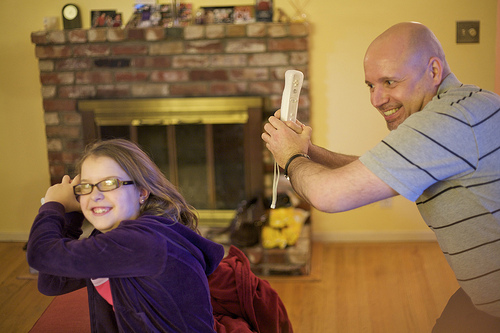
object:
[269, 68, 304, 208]
controller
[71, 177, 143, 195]
eyeglasses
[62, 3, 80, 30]
clock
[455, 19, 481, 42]
light switch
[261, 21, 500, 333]
man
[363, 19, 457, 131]
head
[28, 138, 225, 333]
girl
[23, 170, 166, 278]
arm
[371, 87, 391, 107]
nose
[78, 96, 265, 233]
gold trim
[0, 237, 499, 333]
floor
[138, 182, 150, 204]
ear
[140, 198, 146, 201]
earrings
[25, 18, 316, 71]
mantel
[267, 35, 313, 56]
bricks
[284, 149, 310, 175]
watch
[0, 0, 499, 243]
wall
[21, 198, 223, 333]
jacket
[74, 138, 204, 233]
hair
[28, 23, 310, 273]
fireplace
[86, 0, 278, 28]
photos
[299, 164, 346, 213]
elbow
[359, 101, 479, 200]
sleeve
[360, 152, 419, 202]
edge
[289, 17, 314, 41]
corner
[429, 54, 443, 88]
ear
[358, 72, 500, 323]
shirt